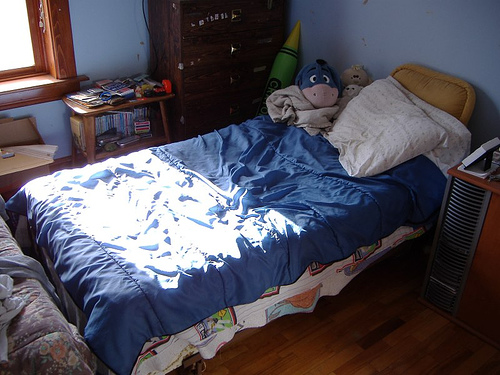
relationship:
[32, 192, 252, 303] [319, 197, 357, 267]
light shining on bed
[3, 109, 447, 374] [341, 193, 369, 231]
comforter on bed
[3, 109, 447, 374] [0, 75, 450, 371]
comforter covering bed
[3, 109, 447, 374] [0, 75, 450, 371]
comforter on bed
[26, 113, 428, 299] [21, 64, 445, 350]
mattress covering bed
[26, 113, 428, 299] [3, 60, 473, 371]
mattress covering bed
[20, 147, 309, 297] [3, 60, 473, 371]
sun shine on bed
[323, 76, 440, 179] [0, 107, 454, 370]
pillow on bed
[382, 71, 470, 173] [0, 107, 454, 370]
pillow on bed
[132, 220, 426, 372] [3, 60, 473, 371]
sheet on bed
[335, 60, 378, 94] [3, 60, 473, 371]
teddy bear on bed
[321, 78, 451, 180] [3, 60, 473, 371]
pillow on bed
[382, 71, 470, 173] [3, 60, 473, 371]
pillow on bed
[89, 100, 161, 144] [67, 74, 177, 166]
books on bookshelf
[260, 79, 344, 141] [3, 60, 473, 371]
towel on bed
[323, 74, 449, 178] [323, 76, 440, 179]
pillowcase on pillow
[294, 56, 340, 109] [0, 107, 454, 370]
eeyore on bed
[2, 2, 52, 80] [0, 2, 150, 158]
window on wall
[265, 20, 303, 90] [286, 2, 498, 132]
crayon near wall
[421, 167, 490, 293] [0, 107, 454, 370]
vent next to bed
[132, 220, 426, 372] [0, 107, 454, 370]
sheet hanging off bed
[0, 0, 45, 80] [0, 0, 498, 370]
window in room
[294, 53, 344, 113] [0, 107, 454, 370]
eeyore on bed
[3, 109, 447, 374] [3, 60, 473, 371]
comforter covering a bed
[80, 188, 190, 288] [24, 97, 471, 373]
comforter covering bed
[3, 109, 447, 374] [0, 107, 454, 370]
comforter covering bed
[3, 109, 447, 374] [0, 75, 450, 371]
comforter covering a bed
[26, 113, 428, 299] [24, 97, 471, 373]
mattress covering a bed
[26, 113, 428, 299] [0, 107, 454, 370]
mattress covering a bed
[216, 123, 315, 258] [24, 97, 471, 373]
mattress covering a bed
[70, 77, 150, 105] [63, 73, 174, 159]
magazines on top of table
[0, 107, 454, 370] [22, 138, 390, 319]
bed with sheets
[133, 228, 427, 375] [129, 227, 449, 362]
sheet under sheets